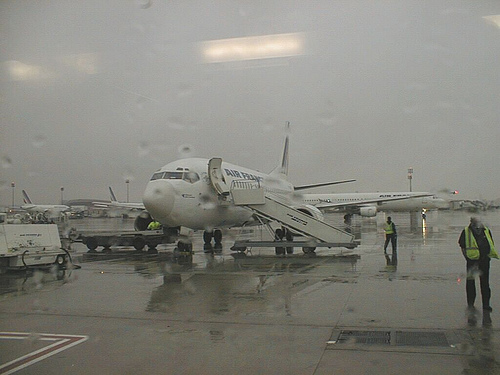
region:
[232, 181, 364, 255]
steps to a plane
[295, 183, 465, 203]
a wing of a plane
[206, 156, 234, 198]
the door of a plane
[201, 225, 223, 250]
the landing gear of a plane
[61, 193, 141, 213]
a wing of a plane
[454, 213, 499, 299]
a man wearing a safety vest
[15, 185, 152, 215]
two airplanes in the background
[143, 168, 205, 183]
front windows of a plane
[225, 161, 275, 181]
windows on a plane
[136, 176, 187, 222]
the nose of a plane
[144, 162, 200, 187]
the windshield of a plane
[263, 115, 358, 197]
the tail of a plane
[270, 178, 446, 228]
the wing of a plane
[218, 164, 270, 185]
writing on a plane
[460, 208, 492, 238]
the head of a person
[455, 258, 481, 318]
the leg of a person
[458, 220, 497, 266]
a bright green vest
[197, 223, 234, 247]
the wheel of a plane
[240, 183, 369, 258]
a mobile staircase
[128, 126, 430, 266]
airplane on the tarmac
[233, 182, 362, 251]
set of white stairs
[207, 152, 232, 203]
door is hanging open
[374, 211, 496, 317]
two people standing on the tarmac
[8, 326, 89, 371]
lines painted on the ground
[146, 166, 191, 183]
windows of the cockpit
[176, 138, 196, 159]
drop of water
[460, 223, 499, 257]
neon traffic vest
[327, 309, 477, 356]
vents on the ground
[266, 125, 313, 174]
tail of the plane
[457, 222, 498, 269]
a neon green vest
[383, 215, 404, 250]
a man walks on the runway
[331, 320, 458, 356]
a drain on the ground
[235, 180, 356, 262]
a stairlift for the plane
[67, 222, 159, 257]
a flat bed trailer.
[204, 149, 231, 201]
the plane door is open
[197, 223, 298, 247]
the tires of the air plane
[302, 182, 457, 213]
the wing of the plane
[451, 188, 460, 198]
the red light on the plane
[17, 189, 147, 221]
the planes in the distance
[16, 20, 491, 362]
This is an airport scene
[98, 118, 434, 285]
A passenger jet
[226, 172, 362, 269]
This is a mobile stairway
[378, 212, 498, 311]
These people are airport ground crew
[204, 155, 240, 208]
The airplane's door is open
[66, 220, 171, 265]
This is a baggage hauler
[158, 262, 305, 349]
The ground is wet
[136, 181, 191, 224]
The jet's nose cone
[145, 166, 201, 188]
These are cockpit windows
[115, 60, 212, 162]
The sky is overcast